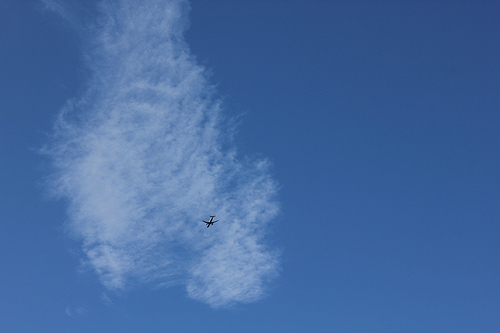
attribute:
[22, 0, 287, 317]
clouds — feathery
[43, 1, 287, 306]
cloud — Large , wispy, Small, thin, puffy 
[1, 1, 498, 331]
blue sky — blue 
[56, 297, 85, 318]
cloud — Small , thin 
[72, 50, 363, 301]
sky — blue 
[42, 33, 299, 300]
cloud — dissipating